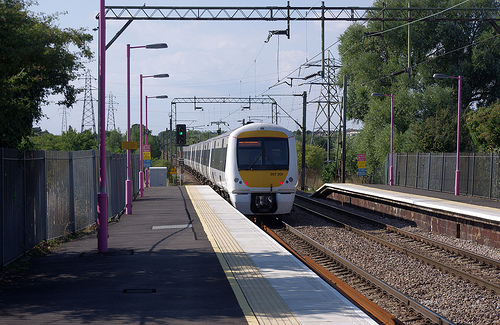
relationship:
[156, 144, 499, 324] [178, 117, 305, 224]
tracks for train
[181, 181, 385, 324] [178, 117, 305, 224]
platform for train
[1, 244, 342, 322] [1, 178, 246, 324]
shadow on ground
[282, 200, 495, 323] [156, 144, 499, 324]
graval between tracks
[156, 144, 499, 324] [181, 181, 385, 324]
tracks near platform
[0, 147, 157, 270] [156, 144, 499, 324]
fencing near tracks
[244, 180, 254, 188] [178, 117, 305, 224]
light on train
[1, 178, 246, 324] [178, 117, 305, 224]
sidewalk near train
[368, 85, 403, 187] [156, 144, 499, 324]
light over tracks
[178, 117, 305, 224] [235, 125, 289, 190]
train has accents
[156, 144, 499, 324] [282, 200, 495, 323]
tracks have graval